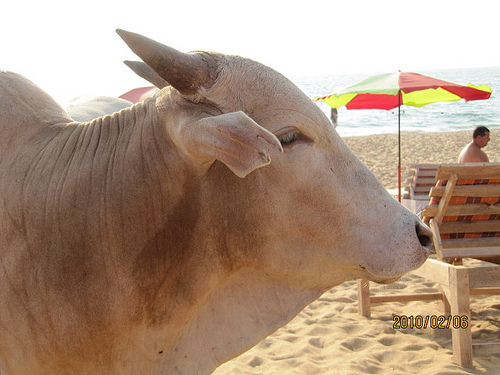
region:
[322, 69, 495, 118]
The yellow and red umbrella.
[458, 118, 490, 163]
The man sitting on the bench.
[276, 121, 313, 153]
The eye of the cow.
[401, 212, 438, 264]
The nostril of the cow.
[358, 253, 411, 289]
The mouth of the cow.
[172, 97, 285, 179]
The ear of the cow.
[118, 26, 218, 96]
The horns on the cow's head.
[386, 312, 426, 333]
The year on the date stamp.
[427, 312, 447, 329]
The month of the date stamp.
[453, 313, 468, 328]
The date on the date stamp.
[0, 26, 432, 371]
a brown Brahma cow on a beach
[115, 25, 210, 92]
the Brahma cows horns are sharp and pointy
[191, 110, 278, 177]
the Brahma cows ear has a piece clipped off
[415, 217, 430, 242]
the Brahma cows nose is pink with black nostril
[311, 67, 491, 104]
a red and yellow beach umbrella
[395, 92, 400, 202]
a beach umbrella pole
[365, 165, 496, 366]
a wooden beach chair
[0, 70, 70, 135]
the Brahma cows fatty deposit hump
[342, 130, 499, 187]
a soft sandy beach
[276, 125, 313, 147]
the Brahma cows eyelashes are white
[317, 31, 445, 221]
Umbrella on tall pole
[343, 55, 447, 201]
Red and yellow umbrella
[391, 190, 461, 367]
Lay out chair on sand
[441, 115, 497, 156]
Man has dark hair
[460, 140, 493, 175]
No shirt on man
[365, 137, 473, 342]
Chairs are on beach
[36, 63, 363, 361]
Animal is on beach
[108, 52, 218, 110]
Animal has two horns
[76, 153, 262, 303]
Animal is large and light brown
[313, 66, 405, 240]
Water in the distance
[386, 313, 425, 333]
this is the number 2010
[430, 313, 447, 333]
this is the number 02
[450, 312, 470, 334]
this is the number 06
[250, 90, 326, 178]
this is a cow eye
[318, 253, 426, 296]
this is a mouth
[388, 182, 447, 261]
this is a nose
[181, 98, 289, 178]
this is an ear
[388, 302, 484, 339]
this is a date stamp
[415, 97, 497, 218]
this is a human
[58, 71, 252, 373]
this is a cow neck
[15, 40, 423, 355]
A big brown cow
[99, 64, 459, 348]
A big cow on a beach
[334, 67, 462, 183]
An umbrella on a beach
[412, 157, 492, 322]
A chair on a beach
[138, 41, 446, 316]
The head of a cow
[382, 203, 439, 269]
The nose of a cow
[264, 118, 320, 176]
The eye of a cow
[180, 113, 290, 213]
The ear of a cow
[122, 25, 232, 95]
Horns on a cow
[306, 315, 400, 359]
Sand